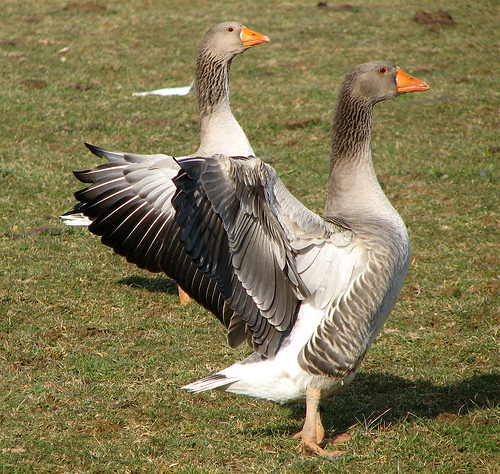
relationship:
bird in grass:
[58, 58, 427, 458] [2, 0, 497, 470]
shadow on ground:
[235, 367, 484, 457] [2, 3, 483, 470]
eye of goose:
[375, 67, 389, 74] [73, 58, 433, 458]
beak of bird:
[395, 71, 429, 94] [187, 58, 427, 458]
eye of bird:
[375, 67, 389, 74] [73, 56, 429, 454]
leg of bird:
[295, 384, 331, 458] [73, 56, 429, 454]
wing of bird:
[162, 154, 314, 357] [187, 58, 427, 458]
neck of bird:
[333, 78, 371, 183] [187, 58, 427, 458]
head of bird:
[333, 58, 429, 112] [187, 58, 427, 458]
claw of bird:
[302, 433, 345, 462] [169, 64, 434, 453]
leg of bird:
[295, 384, 331, 458] [187, 58, 427, 458]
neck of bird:
[191, 49, 234, 121] [69, 22, 269, 305]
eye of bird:
[227, 24, 234, 34] [69, 22, 269, 305]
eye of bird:
[375, 67, 389, 74] [169, 64, 434, 453]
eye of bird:
[375, 67, 389, 74] [187, 58, 427, 458]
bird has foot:
[58, 58, 427, 458] [297, 425, 339, 458]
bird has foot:
[58, 58, 427, 458] [307, 413, 322, 453]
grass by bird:
[2, 0, 497, 470] [58, 58, 427, 458]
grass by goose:
[2, 0, 497, 470] [56, 18, 272, 376]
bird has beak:
[58, 58, 427, 458] [393, 63, 430, 93]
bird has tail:
[58, 58, 427, 458] [179, 370, 238, 401]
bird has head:
[57, 22, 269, 305] [195, 15, 269, 66]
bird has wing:
[58, 58, 427, 458] [170, 153, 283, 364]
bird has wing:
[58, 58, 427, 458] [200, 153, 331, 333]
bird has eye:
[57, 22, 269, 305] [225, 26, 234, 34]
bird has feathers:
[57, 22, 269, 305] [65, 143, 181, 279]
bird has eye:
[58, 58, 427, 458] [375, 63, 388, 78]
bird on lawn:
[58, 58, 427, 458] [0, 4, 499, 469]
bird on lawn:
[57, 22, 269, 305] [0, 4, 499, 469]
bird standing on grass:
[58, 58, 427, 458] [2, 0, 497, 470]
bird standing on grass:
[57, 22, 269, 305] [2, 0, 497, 470]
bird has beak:
[57, 22, 269, 305] [236, 23, 270, 52]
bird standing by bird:
[58, 58, 427, 458] [57, 22, 269, 305]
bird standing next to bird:
[58, 58, 427, 458] [57, 22, 269, 305]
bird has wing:
[58, 58, 427, 458] [195, 154, 315, 334]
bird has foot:
[58, 58, 427, 458] [290, 434, 343, 460]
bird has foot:
[58, 58, 427, 458] [291, 417, 325, 444]